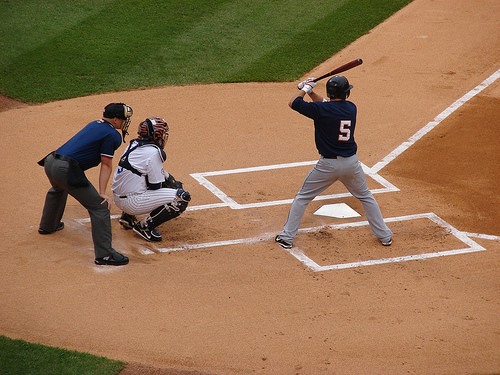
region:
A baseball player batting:
[272, 55, 393, 252]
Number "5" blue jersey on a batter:
[290, 96, 355, 156]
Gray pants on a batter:
[275, 155, 390, 240]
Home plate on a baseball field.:
[312, 201, 358, 217]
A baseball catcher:
[112, 117, 192, 242]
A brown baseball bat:
[301, 57, 365, 84]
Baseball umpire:
[36, 101, 134, 266]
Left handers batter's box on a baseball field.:
[276, 210, 486, 270]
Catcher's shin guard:
[140, 190, 191, 231]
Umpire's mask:
[121, 102, 135, 139]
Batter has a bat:
[263, 46, 410, 270]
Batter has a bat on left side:
[262, 51, 415, 267]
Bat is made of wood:
[287, 49, 378, 94]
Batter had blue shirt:
[263, 68, 410, 253]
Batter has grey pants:
[269, 48, 404, 258]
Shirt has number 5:
[291, 89, 372, 164]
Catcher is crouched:
[104, 108, 201, 250]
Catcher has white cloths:
[107, 111, 209, 247]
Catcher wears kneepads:
[171, 177, 193, 217]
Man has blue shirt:
[27, 84, 139, 281]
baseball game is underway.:
[40, 30, 460, 330]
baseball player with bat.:
[255, 10, 420, 277]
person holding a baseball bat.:
[281, 40, 368, 160]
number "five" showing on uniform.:
[326, 106, 356, 151]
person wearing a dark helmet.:
[316, 75, 361, 105]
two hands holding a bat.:
[286, 57, 322, 97]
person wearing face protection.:
[100, 80, 132, 145]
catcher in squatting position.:
[116, 110, 203, 251]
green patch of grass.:
[25, 11, 267, 72]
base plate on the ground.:
[307, 197, 367, 220]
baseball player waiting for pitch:
[285, 51, 392, 256]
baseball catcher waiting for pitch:
[115, 102, 185, 247]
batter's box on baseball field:
[262, 210, 469, 266]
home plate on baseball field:
[302, 195, 362, 225]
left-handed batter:
[282, 56, 397, 252]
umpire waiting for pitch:
[26, 95, 132, 262]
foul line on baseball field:
[413, 61, 483, 153]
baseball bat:
[293, 60, 373, 83]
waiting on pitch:
[31, 46, 416, 269]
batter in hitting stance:
[283, 52, 399, 253]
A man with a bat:
[256, 42, 416, 271]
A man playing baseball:
[286, 41, 402, 260]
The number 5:
[325, 118, 380, 164]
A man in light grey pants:
[276, 66, 397, 258]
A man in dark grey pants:
[33, 96, 121, 268]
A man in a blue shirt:
[37, 86, 128, 261]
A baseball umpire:
[17, 98, 134, 307]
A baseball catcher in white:
[126, 110, 191, 289]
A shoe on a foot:
[70, 233, 156, 290]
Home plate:
[281, 171, 373, 251]